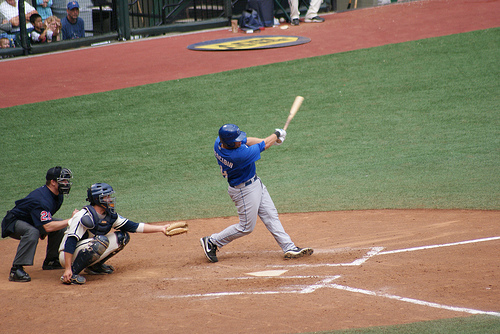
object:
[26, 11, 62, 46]
kid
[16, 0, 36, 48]
stands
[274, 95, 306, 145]
bat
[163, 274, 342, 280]
line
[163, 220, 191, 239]
glove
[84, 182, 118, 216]
helmet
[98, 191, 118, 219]
mask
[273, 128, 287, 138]
glove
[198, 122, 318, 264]
baseball player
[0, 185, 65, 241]
black shirt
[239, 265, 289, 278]
white base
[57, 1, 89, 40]
man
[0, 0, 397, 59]
stand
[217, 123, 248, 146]
helmet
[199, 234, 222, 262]
feet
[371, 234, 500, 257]
white line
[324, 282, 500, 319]
white line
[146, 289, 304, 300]
white line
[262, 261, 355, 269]
white line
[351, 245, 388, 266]
white line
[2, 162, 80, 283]
man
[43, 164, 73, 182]
helmet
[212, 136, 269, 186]
shirt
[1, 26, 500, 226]
grass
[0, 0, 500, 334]
field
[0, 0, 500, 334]
baseball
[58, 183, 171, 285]
catcher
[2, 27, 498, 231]
section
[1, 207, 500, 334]
ground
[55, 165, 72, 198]
guard